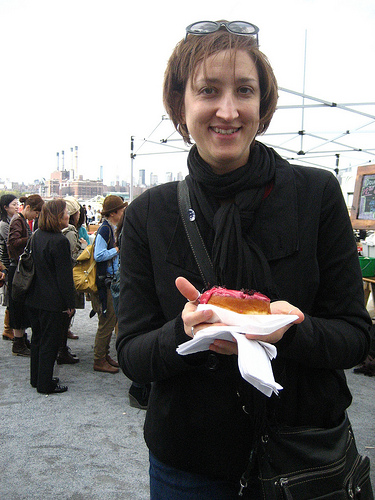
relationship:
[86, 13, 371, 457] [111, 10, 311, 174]
woman has head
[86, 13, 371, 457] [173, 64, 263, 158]
woman has face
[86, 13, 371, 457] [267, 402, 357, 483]
woman has purse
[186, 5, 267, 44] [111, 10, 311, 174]
glasses on head